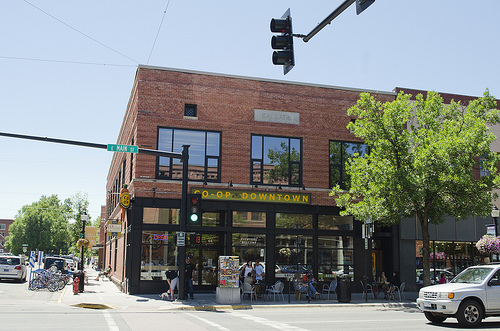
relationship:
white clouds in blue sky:
[24, 45, 97, 125] [1, 0, 498, 220]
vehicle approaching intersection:
[412, 245, 498, 329] [2, 298, 194, 328]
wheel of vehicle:
[456, 296, 486, 328] [415, 264, 500, 328]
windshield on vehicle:
[451, 267, 493, 284] [415, 264, 500, 328]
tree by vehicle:
[326, 88, 496, 318] [415, 264, 500, 328]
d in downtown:
[239, 190, 248, 201] [240, 192, 310, 201]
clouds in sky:
[158, 21, 178, 44] [0, 2, 500, 222]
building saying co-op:
[96, 62, 413, 310] [188, 187, 233, 201]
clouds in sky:
[10, 89, 147, 235] [0, 2, 500, 222]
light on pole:
[261, 8, 307, 78] [278, 0, 395, 50]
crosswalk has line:
[99, 303, 289, 330] [99, 307, 119, 329]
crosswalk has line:
[99, 303, 289, 330] [182, 309, 232, 330]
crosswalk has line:
[99, 303, 289, 330] [227, 304, 301, 329]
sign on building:
[144, 173, 381, 260] [86, 63, 497, 303]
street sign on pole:
[103, 139, 137, 156] [0, 130, 182, 159]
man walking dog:
[164, 267, 181, 299] [157, 287, 172, 302]